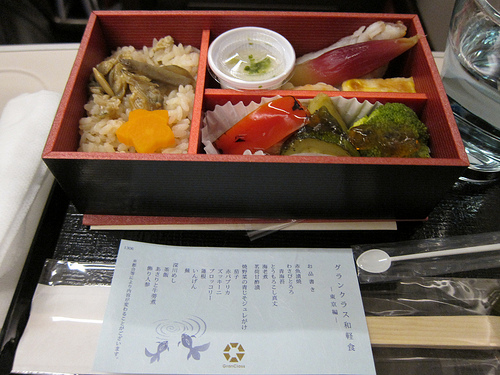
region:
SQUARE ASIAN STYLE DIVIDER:
[74, 11, 450, 191]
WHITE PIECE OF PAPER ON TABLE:
[119, 243, 358, 373]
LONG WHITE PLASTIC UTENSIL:
[347, 245, 494, 281]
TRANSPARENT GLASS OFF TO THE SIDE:
[443, 10, 496, 121]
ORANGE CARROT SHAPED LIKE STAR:
[115, 110, 180, 151]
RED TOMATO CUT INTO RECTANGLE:
[216, 90, 297, 152]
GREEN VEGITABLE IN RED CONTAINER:
[352, 102, 412, 143]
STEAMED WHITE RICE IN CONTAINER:
[105, 32, 200, 148]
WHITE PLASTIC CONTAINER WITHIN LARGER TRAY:
[208, 30, 288, 80]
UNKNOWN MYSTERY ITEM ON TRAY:
[308, 45, 421, 87]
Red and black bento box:
[41, 5, 475, 218]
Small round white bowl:
[207, 19, 297, 89]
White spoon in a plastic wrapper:
[358, 231, 497, 286]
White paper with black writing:
[82, 227, 381, 369]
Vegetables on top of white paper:
[193, 103, 412, 157]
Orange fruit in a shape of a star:
[111, 97, 181, 162]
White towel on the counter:
[6, 50, 64, 297]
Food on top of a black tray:
[18, 20, 492, 345]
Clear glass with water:
[429, 8, 493, 195]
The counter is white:
[6, 44, 136, 169]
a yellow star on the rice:
[111, 102, 183, 157]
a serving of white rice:
[73, 27, 198, 170]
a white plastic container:
[204, 22, 298, 90]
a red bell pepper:
[209, 90, 312, 160]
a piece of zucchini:
[276, 129, 359, 156]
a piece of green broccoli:
[351, 95, 431, 140]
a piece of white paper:
[85, 235, 380, 373]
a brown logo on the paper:
[218, 337, 252, 372]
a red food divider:
[38, 4, 472, 232]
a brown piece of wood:
[365, 306, 498, 360]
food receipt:
[109, 248, 358, 374]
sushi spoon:
[355, 251, 497, 280]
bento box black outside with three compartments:
[79, 9, 466, 221]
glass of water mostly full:
[444, 13, 496, 150]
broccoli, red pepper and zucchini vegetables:
[216, 109, 436, 160]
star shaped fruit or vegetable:
[117, 108, 185, 152]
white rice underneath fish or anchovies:
[101, 39, 198, 115]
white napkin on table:
[8, 89, 45, 206]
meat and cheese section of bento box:
[211, 24, 418, 89]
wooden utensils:
[370, 301, 484, 373]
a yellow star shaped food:
[118, 106, 178, 153]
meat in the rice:
[88, 55, 196, 110]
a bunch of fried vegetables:
[211, 96, 431, 156]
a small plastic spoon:
[352, 243, 498, 275]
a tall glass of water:
[444, 1, 499, 186]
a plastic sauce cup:
[208, 27, 298, 90]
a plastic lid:
[203, 26, 296, 88]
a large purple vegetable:
[296, 22, 421, 91]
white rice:
[79, 108, 116, 150]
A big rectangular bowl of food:
[41, 11, 468, 221]